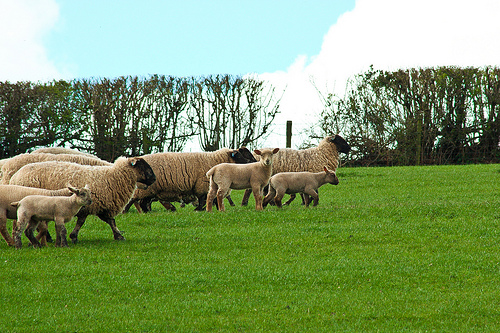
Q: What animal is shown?
A: Sheep.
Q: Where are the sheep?
A: In a field.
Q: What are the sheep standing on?
A: Grass.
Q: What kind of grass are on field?
A: Short green grass.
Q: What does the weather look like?
A: Somewhat cloudy blue sky.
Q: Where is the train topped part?
A: Top chopped.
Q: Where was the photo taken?
A: In a field.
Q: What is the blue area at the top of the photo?
A: The sky.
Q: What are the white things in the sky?
A: Clouds.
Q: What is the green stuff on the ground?
A: Grass.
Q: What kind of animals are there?
A: Sheep.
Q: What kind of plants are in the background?
A: Shrubs.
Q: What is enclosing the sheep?
A: A fence.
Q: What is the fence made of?
A: Wire.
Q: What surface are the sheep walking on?
A: Grass.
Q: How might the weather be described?
A: Partly cloudy.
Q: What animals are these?
A: Sheep.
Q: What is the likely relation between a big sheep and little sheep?
A: Mother and child.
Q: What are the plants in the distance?
A: Bushes.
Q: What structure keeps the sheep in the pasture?
A: A fence.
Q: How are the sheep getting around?
A: By walking.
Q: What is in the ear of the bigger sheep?
A: A tag.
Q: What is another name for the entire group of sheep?
A: A herd.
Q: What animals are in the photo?
A: Sheep.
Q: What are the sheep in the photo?
A: On grass.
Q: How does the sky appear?
A: Cloudy.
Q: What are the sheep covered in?
A: Wool.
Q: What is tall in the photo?
A: Trees.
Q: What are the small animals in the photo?
A: Lambs.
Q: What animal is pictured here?
A: Sheep.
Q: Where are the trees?
A: Behind the sheep.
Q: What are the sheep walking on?
A: Grass.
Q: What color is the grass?
A: Green.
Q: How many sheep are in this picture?
A: 10.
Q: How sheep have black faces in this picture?
A: 3.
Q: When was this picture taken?
A: Daytime.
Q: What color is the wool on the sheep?
A: White.